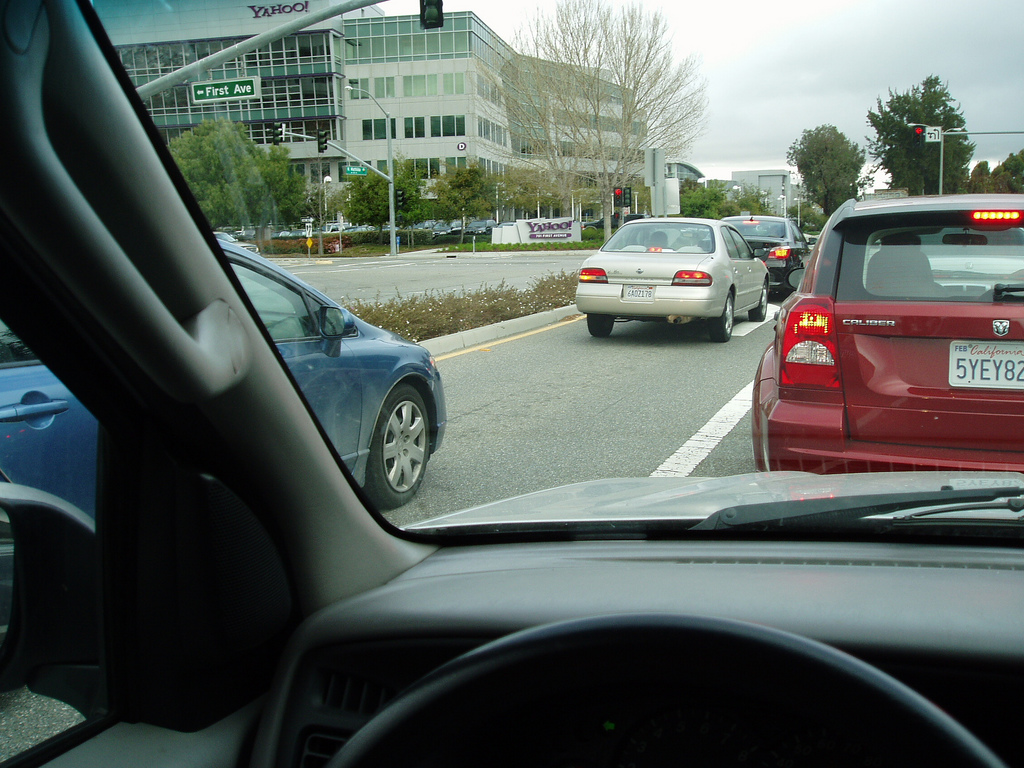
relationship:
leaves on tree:
[671, 177, 742, 222] [678, 174, 748, 228]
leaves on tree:
[796, 129, 864, 209] [785, 121, 874, 214]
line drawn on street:
[649, 383, 752, 476] [441, 314, 758, 473]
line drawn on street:
[428, 311, 587, 363] [1, 248, 782, 765]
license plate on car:
[943, 340, 1021, 408] [568, 208, 773, 347]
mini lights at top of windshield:
[972, 207, 1021, 224] [836, 224, 1021, 305]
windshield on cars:
[836, 224, 1021, 305] [743, 193, 1024, 484]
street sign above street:
[190, 71, 279, 106] [264, 240, 1011, 523]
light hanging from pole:
[906, 112, 926, 155] [933, 121, 946, 195]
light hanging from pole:
[417, 0, 453, 26] [135, 0, 391, 71]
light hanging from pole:
[610, 181, 633, 207] [619, 193, 623, 225]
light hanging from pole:
[265, 114, 284, 147] [312, 158, 331, 245]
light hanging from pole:
[312, 123, 328, 152] [385, 175, 399, 246]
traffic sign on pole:
[904, 120, 942, 143] [935, 144, 946, 195]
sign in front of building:
[515, 215, 593, 251] [117, 1, 680, 229]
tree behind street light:
[860, 64, 978, 189] [899, 117, 948, 144]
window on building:
[364, 125, 421, 145] [337, 20, 654, 217]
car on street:
[743, 183, 1022, 484] [323, 241, 833, 536]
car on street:
[21, 196, 470, 526] [520, 336, 714, 473]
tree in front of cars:
[792, 120, 875, 204] [577, 193, 1021, 466]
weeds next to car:
[403, 286, 574, 332] [576, 212, 767, 336]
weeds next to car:
[403, 286, 574, 332] [722, 212, 818, 302]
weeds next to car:
[403, 286, 574, 332] [7, 228, 437, 516]